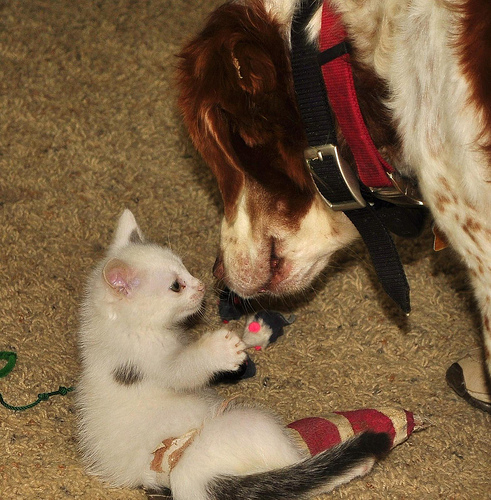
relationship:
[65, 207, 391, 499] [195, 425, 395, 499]
cat has tail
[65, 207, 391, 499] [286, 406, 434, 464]
kitten has toy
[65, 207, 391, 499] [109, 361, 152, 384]
kitten has spot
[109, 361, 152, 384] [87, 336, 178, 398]
spot on shoulder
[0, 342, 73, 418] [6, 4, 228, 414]
string in on ground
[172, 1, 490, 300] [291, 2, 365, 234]
dog has collar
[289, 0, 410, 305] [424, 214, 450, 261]
collar has tags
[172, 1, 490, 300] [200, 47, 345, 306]
dog has face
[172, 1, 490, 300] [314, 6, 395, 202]
dog has collar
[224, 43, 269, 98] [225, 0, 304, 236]
something in hair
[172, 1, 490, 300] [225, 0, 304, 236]
dog has hair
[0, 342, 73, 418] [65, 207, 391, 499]
string around kitten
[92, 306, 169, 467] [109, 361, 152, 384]
fur has spots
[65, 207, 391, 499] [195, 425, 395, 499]
kitten has tail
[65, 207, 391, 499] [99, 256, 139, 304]
kitten has ear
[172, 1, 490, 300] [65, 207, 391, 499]
dog sniffing kitten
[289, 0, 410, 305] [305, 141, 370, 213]
collar has buckle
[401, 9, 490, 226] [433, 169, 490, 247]
fur has spots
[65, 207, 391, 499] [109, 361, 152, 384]
cat has spot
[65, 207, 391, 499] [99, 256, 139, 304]
cat has ear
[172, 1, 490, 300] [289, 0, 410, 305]
dog has collar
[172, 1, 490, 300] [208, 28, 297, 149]
dog has ear